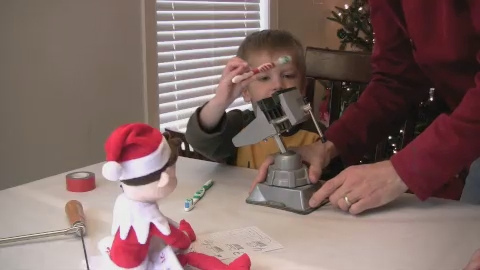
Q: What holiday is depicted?
A: Christmas.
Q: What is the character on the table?
A: Elf.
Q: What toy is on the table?
A: Elf on the Shelf.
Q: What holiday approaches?
A: Christmas.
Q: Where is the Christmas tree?
A: Behind the boy's chair.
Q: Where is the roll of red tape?
A: On the table.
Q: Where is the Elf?
A: On the table.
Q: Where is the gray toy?
A: On the table.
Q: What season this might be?
A: Winter.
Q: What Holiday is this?
A: Christmas.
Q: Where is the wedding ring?
A: On the lady's hand?.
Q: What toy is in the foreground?
A: An elf.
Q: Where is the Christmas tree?
A: Behind the people.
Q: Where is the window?
A: Behind the boy.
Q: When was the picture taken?
A: During the daytime.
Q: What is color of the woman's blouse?
A: Red.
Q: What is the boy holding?
A: Toothbrush.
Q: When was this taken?
A: During the day.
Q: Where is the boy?
A: At the table.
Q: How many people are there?
A: Two.